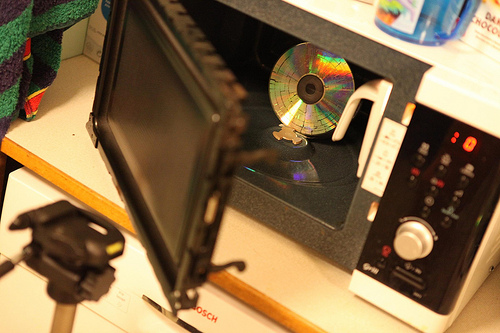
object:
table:
[0, 52, 500, 333]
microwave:
[92, 4, 496, 326]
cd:
[269, 41, 357, 141]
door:
[90, 8, 237, 284]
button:
[456, 164, 478, 179]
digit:
[447, 127, 483, 151]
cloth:
[0, 0, 97, 131]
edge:
[339, 271, 433, 331]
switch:
[393, 209, 444, 271]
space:
[188, 14, 280, 103]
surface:
[1, 94, 68, 174]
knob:
[394, 218, 434, 259]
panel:
[389, 99, 498, 320]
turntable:
[273, 118, 303, 144]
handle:
[327, 81, 395, 175]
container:
[376, 2, 476, 44]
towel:
[3, 5, 90, 138]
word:
[186, 303, 223, 325]